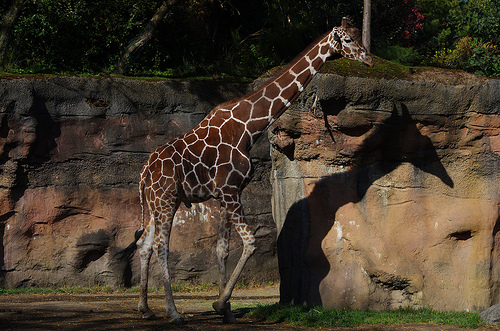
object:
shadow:
[263, 103, 453, 316]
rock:
[267, 70, 499, 315]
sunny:
[320, 176, 498, 305]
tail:
[111, 176, 146, 265]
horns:
[342, 17, 351, 30]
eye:
[344, 38, 352, 44]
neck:
[240, 52, 337, 132]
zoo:
[0, 0, 499, 331]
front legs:
[212, 194, 257, 302]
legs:
[135, 199, 179, 309]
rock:
[0, 72, 277, 289]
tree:
[107, 0, 183, 74]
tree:
[361, 0, 377, 51]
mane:
[217, 29, 336, 113]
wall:
[0, 75, 499, 315]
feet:
[137, 296, 237, 328]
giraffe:
[104, 17, 373, 326]